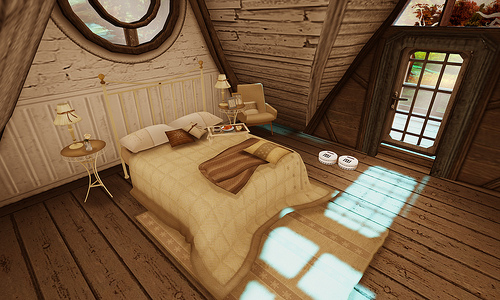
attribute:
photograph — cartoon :
[6, 6, 498, 298]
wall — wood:
[203, 0, 390, 126]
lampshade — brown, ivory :
[36, 84, 113, 154]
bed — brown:
[130, 101, 335, 251]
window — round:
[53, 2, 193, 71]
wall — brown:
[0, 0, 252, 209]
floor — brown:
[336, 173, 480, 298]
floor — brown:
[53, 208, 147, 288]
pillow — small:
[240, 136, 295, 165]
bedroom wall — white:
[49, 57, 120, 83]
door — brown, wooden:
[380, 45, 465, 162]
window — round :
[71, 0, 180, 73]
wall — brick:
[46, 51, 89, 83]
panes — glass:
[401, 46, 455, 155]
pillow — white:
[121, 115, 179, 151]